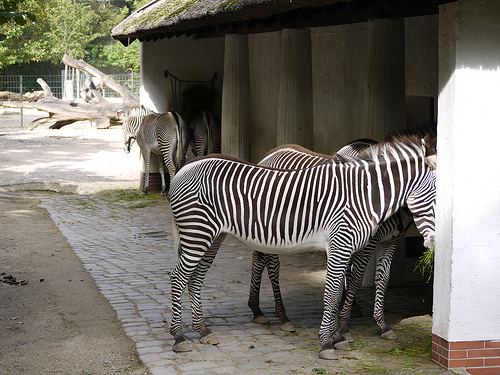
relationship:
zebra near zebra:
[158, 127, 438, 362] [230, 136, 437, 343]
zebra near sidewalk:
[95, 92, 189, 190] [0, 96, 168, 370]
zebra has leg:
[158, 127, 438, 362] [318, 245, 350, 360]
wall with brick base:
[465, 47, 499, 285] [425, 331, 482, 370]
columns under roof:
[213, 14, 410, 160] [110, 1, 390, 37]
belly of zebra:
[239, 236, 322, 255] [158, 127, 438, 362]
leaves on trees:
[8, 0, 105, 58] [0, 0, 138, 74]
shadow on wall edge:
[421, 52, 491, 139] [426, 4, 464, 344]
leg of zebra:
[372, 239, 407, 350] [252, 172, 398, 314]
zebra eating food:
[158, 127, 438, 362] [419, 237, 438, 282]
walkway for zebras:
[59, 190, 280, 372] [162, 130, 440, 358]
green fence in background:
[1, 71, 141, 127] [2, 0, 142, 190]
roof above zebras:
[100, 4, 491, 42] [124, 108, 438, 363]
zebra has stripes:
[158, 127, 438, 362] [168, 133, 423, 344]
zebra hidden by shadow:
[89, 83, 187, 207] [176, 98, 220, 152]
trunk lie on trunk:
[5, 95, 130, 134] [14, 72, 146, 124]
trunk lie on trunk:
[5, 95, 130, 134] [56, 49, 141, 116]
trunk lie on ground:
[5, 95, 130, 134] [4, 100, 474, 372]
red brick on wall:
[427, 334, 483, 370] [431, 332, 499, 374]